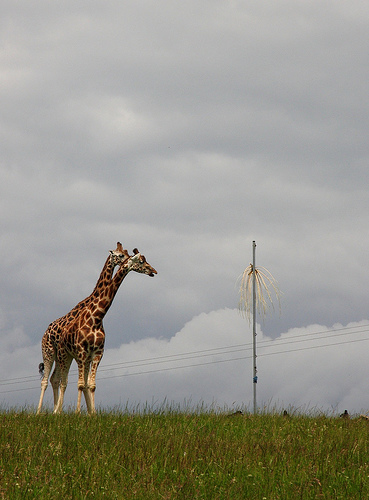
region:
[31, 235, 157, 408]
these are the giraffes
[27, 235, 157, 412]
the giraffes are standing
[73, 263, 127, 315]
these are the necks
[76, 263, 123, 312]
the neck is long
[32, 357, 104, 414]
these are the legs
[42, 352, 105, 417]
the legs are long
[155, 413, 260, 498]
the grass are long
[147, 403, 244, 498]
the grass are green in color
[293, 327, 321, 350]
these are the electric lines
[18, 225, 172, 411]
two giraffes standing in field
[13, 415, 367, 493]
ground covered in tall grass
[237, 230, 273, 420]
silver metal pole in field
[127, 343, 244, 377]
electric lines hanging above field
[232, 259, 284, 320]
brown hay attached to metal pole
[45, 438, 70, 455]
brown seeds on grass stem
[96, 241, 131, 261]
head of a giraffe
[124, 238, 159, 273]
head of a giraffe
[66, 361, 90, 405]
leg of a giraffe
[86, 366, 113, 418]
leg of a giraffe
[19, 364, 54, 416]
leg of a giraffe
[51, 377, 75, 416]
leg of a giraffe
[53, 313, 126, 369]
body of a giraffe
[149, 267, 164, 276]
mouth of a giraffe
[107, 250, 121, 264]
ear of a giraffe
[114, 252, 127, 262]
eye of a giraffe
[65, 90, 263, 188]
the sky is overcast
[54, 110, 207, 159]
the sky is overcast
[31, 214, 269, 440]
two giraffes eyeing the pole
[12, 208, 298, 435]
two giraffes eyeing the pole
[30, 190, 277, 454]
two giraffes eyeing the pole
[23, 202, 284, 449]
two giraffes eyeing the pole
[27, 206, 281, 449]
two giraffes eyeing the pole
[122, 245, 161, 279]
head of a giraffe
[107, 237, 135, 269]
head of a giraffe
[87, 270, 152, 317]
neck of a giraffe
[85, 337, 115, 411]
leg of a giraffe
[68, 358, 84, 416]
leg of a giraffe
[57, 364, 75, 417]
leg of a giraffe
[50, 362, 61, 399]
leg of a giraffe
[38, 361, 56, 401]
leg of a giraffe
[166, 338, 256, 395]
clouds in the sky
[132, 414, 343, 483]
bunch of grass on a field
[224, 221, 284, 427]
pole with hay hanging from it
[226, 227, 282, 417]
pole with hay hanging from it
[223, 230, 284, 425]
pole with hay hanging from it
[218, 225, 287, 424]
pole with hay hanging from it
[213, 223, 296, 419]
pole with hay hanging from it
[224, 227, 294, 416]
pole with hay hanging from it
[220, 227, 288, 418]
pole with hay hanging from it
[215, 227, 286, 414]
pole with hay hanging from it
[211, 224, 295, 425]
pole with hay hanging from it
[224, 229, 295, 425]
pole with hay hanging from it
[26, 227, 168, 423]
two zebras looking ahead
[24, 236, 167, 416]
two zebras looking ahead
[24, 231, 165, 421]
two zebras looking ahead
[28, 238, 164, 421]
two zebras looking ahead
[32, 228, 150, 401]
two giraffes in the field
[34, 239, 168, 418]
two giraffes in the field